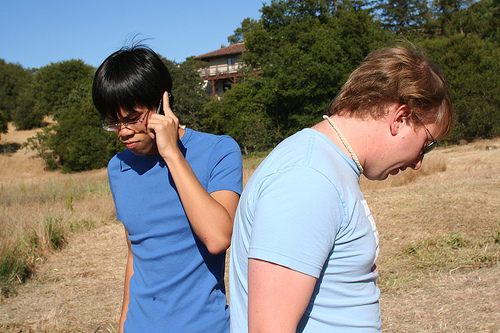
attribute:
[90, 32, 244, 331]
asian man — asian 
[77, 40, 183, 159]
hair — black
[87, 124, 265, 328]
shirt — blue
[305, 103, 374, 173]
necklace — white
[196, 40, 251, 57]
roof — brown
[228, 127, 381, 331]
shirt — blue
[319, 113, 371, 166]
necklace — white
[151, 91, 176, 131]
phone — cell 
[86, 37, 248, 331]
man — blue 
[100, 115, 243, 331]
shirt — light blue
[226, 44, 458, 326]
man — wire rimmed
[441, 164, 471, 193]
grass — brown, tall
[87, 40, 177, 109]
hair — short, black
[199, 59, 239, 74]
floor — second 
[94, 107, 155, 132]
glasses — rimmed